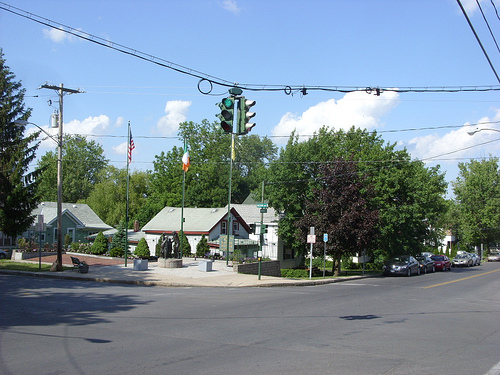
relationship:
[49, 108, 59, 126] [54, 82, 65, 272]
transformer on pole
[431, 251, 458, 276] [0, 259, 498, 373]
red car parked road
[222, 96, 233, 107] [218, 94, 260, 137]
light on streetlight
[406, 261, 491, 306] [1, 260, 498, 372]
line on street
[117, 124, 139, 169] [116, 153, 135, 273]
flags on poles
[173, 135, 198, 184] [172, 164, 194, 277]
flags on poles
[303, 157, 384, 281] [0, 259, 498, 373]
tree on side of road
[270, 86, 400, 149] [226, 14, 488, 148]
cloud in sky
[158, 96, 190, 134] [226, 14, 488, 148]
cloud in sky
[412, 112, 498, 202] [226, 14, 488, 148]
cloud in sky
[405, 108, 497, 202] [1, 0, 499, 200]
cloud in sky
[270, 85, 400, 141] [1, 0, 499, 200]
cloud in sky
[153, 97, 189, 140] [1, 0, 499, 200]
cloud in sky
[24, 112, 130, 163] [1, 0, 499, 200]
cloud in sky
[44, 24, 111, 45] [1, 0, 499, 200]
cloud in sky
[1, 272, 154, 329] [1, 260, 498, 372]
shadow on street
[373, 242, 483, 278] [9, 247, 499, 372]
parked cars on side of road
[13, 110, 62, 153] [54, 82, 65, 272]
light on pole